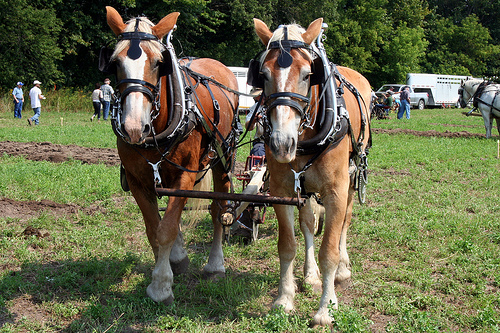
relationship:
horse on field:
[248, 17, 371, 331] [386, 135, 498, 318]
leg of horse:
[271, 171, 298, 299] [248, 17, 371, 331]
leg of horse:
[264, 171, 298, 313] [248, 17, 371, 331]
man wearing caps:
[26, 80, 51, 126] [6, 77, 42, 87]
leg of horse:
[480, 111, 491, 138] [455, 73, 499, 136]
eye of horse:
[302, 70, 312, 82] [270, 46, 430, 181]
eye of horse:
[146, 59, 166, 76] [90, 5, 245, 330]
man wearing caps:
[29, 80, 47, 123] [33, 79, 43, 86]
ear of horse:
[298, 17, 323, 44] [248, 17, 371, 331]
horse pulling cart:
[98, 5, 243, 307] [225, 108, 375, 247]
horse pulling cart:
[248, 17, 371, 331] [225, 108, 375, 247]